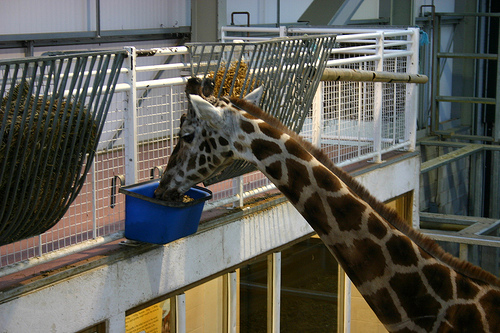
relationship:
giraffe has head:
[153, 73, 499, 333] [152, 72, 272, 212]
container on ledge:
[114, 175, 212, 246] [3, 141, 423, 332]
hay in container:
[2, 83, 102, 251] [114, 175, 212, 246]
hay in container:
[204, 56, 269, 119] [185, 37, 339, 185]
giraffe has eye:
[153, 73, 499, 333] [180, 129, 195, 144]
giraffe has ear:
[153, 73, 499, 333] [186, 89, 224, 132]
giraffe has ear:
[153, 73, 499, 333] [237, 81, 266, 110]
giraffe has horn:
[153, 73, 499, 333] [185, 75, 202, 104]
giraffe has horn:
[153, 73, 499, 333] [204, 77, 219, 97]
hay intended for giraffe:
[2, 83, 102, 251] [153, 73, 499, 333]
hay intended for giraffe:
[204, 56, 269, 119] [153, 73, 499, 333]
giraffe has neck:
[153, 73, 499, 333] [248, 112, 499, 327]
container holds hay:
[4, 48, 132, 248] [2, 83, 102, 251]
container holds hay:
[185, 37, 339, 185] [204, 56, 269, 119]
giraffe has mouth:
[153, 73, 499, 333] [152, 182, 183, 207]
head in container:
[152, 72, 272, 212] [114, 175, 212, 246]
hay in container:
[2, 83, 102, 251] [4, 48, 132, 248]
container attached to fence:
[114, 175, 212, 246] [2, 26, 429, 285]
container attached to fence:
[4, 48, 132, 248] [2, 26, 429, 285]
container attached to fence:
[185, 37, 339, 185] [2, 26, 429, 285]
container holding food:
[114, 175, 212, 246] [180, 192, 197, 205]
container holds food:
[114, 175, 212, 246] [180, 192, 197, 205]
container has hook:
[114, 175, 212, 246] [109, 171, 124, 212]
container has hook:
[114, 175, 212, 246] [150, 163, 162, 179]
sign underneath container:
[122, 304, 167, 332] [114, 175, 212, 246]